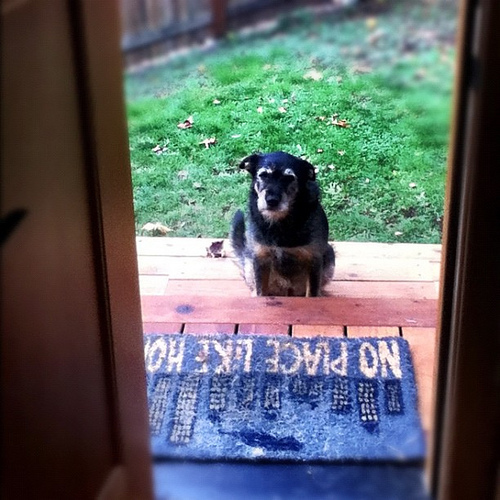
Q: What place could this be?
A: It is a yard.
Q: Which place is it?
A: It is a yard.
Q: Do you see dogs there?
A: Yes, there is a dog.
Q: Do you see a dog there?
A: Yes, there is a dog.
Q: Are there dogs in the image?
A: Yes, there is a dog.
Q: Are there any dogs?
A: Yes, there is a dog.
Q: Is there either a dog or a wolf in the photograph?
A: Yes, there is a dog.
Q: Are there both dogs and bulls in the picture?
A: No, there is a dog but no bulls.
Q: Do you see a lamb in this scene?
A: No, there are no lambs.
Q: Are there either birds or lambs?
A: No, there are no lambs or birds.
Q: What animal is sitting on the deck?
A: The dog is sitting on the deck.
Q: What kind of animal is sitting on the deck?
A: The animal is a dog.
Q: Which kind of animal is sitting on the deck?
A: The animal is a dog.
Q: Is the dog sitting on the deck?
A: Yes, the dog is sitting on the deck.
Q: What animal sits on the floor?
A: The animal is a dog.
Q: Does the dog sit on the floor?
A: Yes, the dog sits on the floor.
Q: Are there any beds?
A: No, there are no beds.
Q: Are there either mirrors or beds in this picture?
A: No, there are no beds or mirrors.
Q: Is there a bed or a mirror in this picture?
A: No, there are no beds or mirrors.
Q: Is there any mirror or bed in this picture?
A: No, there are no beds or mirrors.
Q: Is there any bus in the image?
A: No, there are no buses.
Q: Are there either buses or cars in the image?
A: No, there are no buses or cars.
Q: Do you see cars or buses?
A: No, there are no buses or cars.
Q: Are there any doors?
A: Yes, there is a door.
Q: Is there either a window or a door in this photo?
A: Yes, there is a door.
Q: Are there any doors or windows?
A: Yes, there is a door.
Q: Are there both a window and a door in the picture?
A: No, there is a door but no windows.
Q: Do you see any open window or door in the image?
A: Yes, there is an open door.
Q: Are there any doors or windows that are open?
A: Yes, the door is open.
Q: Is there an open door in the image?
A: Yes, there is an open door.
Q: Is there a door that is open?
A: Yes, there is a door that is open.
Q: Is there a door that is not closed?
A: Yes, there is a open door.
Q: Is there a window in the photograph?
A: No, there are no windows.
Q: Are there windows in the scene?
A: No, there are no windows.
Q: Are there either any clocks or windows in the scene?
A: No, there are no windows or clocks.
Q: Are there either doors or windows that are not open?
A: No, there is a door but it is open.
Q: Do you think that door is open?
A: Yes, the door is open.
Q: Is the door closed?
A: No, the door is open.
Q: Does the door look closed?
A: No, the door is open.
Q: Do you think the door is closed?
A: No, the door is open.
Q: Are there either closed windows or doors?
A: No, there is a door but it is open.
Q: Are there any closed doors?
A: No, there is a door but it is open.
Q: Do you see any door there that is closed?
A: No, there is a door but it is open.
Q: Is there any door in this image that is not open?
A: No, there is a door but it is open.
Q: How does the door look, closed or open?
A: The door is open.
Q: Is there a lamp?
A: No, there are no lamps.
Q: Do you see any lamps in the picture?
A: No, there are no lamps.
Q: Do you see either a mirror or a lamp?
A: No, there are no lamps or mirrors.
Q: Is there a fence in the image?
A: Yes, there is a fence.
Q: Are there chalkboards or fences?
A: Yes, there is a fence.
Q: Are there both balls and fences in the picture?
A: No, there is a fence but no balls.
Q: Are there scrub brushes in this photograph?
A: No, there are no scrub brushes.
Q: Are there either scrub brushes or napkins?
A: No, there are no scrub brushes or napkins.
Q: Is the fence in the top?
A: Yes, the fence is in the top of the image.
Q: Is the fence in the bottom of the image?
A: No, the fence is in the top of the image.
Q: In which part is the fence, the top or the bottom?
A: The fence is in the top of the image.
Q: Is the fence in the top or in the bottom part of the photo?
A: The fence is in the top of the image.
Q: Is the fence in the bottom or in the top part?
A: The fence is in the top of the image.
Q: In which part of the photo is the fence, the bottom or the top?
A: The fence is in the top of the image.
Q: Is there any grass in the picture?
A: Yes, there is grass.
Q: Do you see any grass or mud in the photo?
A: Yes, there is grass.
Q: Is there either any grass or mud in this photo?
A: Yes, there is grass.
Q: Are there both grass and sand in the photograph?
A: No, there is grass but no sand.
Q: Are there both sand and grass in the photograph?
A: No, there is grass but no sand.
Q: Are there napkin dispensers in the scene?
A: No, there are no napkin dispensers.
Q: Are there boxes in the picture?
A: No, there are no boxes.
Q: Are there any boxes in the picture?
A: No, there are no boxes.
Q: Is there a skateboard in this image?
A: No, there are no skateboards.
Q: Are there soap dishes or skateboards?
A: No, there are no skateboards or soap dishes.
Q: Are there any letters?
A: Yes, there are letters.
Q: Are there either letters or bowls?
A: Yes, there are letters.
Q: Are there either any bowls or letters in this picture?
A: Yes, there are letters.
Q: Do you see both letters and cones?
A: No, there are letters but no cones.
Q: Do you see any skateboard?
A: No, there are no skateboards.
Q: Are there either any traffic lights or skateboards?
A: No, there are no skateboards or traffic lights.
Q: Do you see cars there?
A: No, there are no cars.